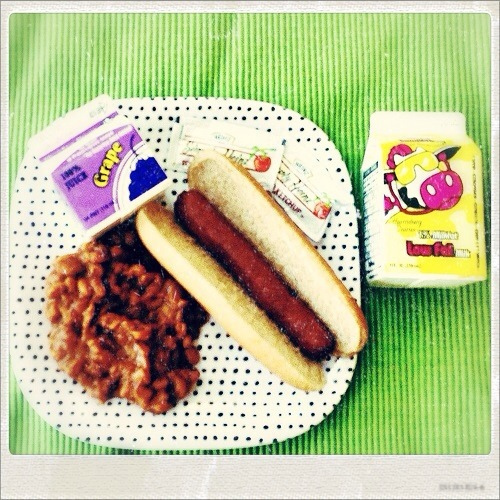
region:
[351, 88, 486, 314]
a small carton of milk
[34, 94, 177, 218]
a carton of juice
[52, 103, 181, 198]
the juice is grape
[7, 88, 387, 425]
a plate on the table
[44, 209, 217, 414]
beans on the plate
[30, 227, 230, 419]
the beans are brown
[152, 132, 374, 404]
the hot dog bread is white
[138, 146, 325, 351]
a hot dog on the plate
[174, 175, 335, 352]
the hot dog is reddish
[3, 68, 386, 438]
the plate has small black dots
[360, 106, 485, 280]
carton of milk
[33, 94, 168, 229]
carton of grape juice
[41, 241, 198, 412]
pile of baked beans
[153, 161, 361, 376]
hotdog in hotdog bun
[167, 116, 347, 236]
packets of ketchup next to hotdog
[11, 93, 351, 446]
white plate with black dots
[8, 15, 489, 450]
green placemat plate is on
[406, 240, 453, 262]
red lettering on milk carton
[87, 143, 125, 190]
yellow lettering on juice carton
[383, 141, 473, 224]
cow cartoon on milk carton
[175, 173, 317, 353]
A hotdog on the plate.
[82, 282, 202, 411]
Beaked beans on the plate.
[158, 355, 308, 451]
Black dots on the plate.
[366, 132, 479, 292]
Milk next to the plate.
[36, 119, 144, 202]
Juice on the plate.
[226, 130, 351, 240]
Packages of ketchup on the plane.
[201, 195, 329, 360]
The weiner is in the bun.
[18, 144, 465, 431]
The plate is sitting on a plate mat.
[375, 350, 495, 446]
The plate mat is green.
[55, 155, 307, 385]
Food on the polka dot plate.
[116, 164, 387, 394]
a hotdog in a bun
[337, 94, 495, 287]
a container of milk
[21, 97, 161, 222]
a container of grape juice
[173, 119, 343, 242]
two packets of ketchup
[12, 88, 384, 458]
a square plate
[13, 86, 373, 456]
a white plate with black dots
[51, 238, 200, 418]
baked beans on a plate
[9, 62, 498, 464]
a green placemat under plate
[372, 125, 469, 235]
a cow on the milk carton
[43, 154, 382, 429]
a hotdog and some beans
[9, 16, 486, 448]
plate on green mat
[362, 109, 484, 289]
carton laying on its side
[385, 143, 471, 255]
cartoon on side of carton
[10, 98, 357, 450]
plate with black dots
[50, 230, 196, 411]
pile of baked beans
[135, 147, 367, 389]
plain hot dog in bun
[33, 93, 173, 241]
carton of fruit juice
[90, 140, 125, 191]
yellow word on purple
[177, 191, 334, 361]
cooked hot dog in bread